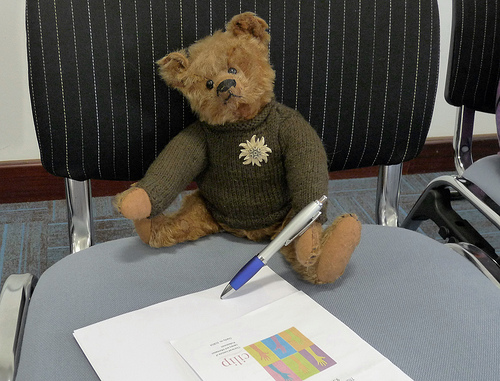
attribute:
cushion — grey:
[10, 211, 498, 379]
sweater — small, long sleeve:
[142, 100, 332, 227]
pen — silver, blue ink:
[219, 192, 328, 299]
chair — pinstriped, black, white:
[25, 3, 439, 277]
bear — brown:
[110, 8, 362, 289]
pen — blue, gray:
[178, 227, 277, 282]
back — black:
[25, 1, 435, 183]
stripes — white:
[25, 1, 432, 176]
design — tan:
[235, 132, 275, 165]